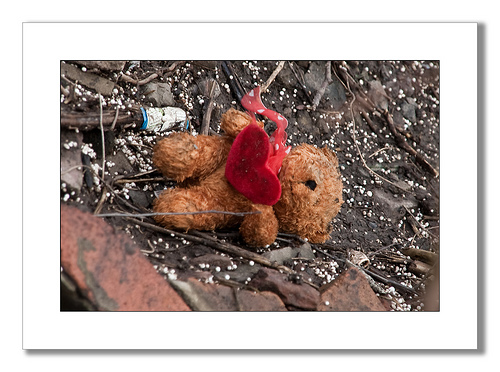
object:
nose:
[305, 179, 317, 191]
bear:
[153, 106, 344, 247]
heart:
[222, 125, 280, 205]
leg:
[152, 130, 200, 182]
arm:
[220, 108, 255, 136]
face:
[284, 153, 332, 226]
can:
[139, 105, 189, 132]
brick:
[61, 201, 193, 312]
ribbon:
[241, 85, 287, 149]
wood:
[62, 62, 116, 96]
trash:
[347, 247, 371, 269]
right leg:
[152, 186, 215, 232]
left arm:
[237, 210, 278, 247]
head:
[280, 142, 344, 241]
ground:
[61, 60, 441, 311]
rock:
[374, 185, 416, 219]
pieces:
[347, 123, 351, 127]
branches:
[260, 62, 285, 94]